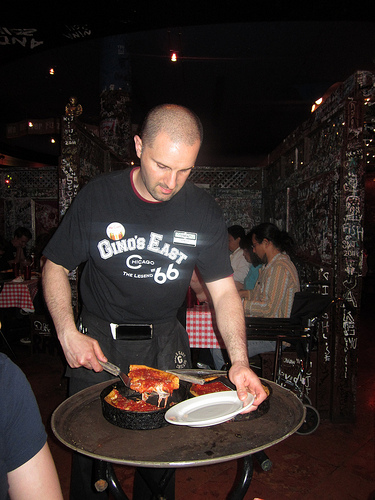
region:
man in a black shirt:
[31, 92, 255, 415]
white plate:
[158, 377, 263, 440]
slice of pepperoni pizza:
[121, 353, 189, 414]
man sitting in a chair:
[214, 212, 314, 381]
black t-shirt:
[40, 156, 237, 346]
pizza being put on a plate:
[46, 352, 324, 472]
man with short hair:
[120, 95, 210, 215]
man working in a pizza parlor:
[34, 95, 278, 432]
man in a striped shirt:
[221, 211, 300, 333]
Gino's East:
[93, 229, 207, 295]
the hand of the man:
[231, 363, 273, 416]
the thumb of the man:
[231, 372, 247, 406]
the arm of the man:
[196, 212, 256, 364]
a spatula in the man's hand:
[81, 351, 166, 401]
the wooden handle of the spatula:
[89, 354, 124, 377]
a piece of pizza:
[121, 359, 183, 402]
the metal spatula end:
[119, 368, 165, 398]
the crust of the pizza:
[128, 360, 183, 391]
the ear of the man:
[259, 234, 271, 250]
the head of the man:
[128, 102, 212, 204]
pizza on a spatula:
[121, 363, 177, 396]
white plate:
[171, 404, 239, 418]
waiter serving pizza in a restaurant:
[112, 105, 187, 408]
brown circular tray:
[50, 372, 305, 461]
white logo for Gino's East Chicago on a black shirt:
[99, 231, 185, 265]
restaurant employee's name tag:
[174, 230, 196, 245]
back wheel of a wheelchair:
[306, 411, 318, 432]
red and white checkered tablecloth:
[189, 311, 212, 346]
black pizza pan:
[119, 411, 161, 426]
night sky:
[164, 5, 355, 46]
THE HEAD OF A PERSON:
[127, 99, 206, 203]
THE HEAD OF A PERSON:
[246, 222, 286, 261]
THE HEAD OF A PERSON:
[225, 222, 242, 253]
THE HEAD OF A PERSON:
[241, 238, 256, 265]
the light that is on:
[304, 96, 325, 116]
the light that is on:
[170, 49, 181, 65]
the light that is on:
[48, 135, 57, 147]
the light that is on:
[25, 117, 34, 128]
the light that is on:
[43, 63, 53, 78]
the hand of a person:
[205, 266, 268, 415]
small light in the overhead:
[152, 40, 206, 70]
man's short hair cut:
[153, 113, 210, 141]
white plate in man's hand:
[157, 393, 256, 433]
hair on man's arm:
[216, 314, 256, 355]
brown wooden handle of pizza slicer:
[82, 356, 129, 380]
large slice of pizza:
[108, 361, 180, 409]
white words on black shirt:
[94, 222, 210, 280]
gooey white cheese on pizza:
[148, 381, 194, 396]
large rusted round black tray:
[53, 354, 299, 486]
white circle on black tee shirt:
[96, 213, 135, 253]